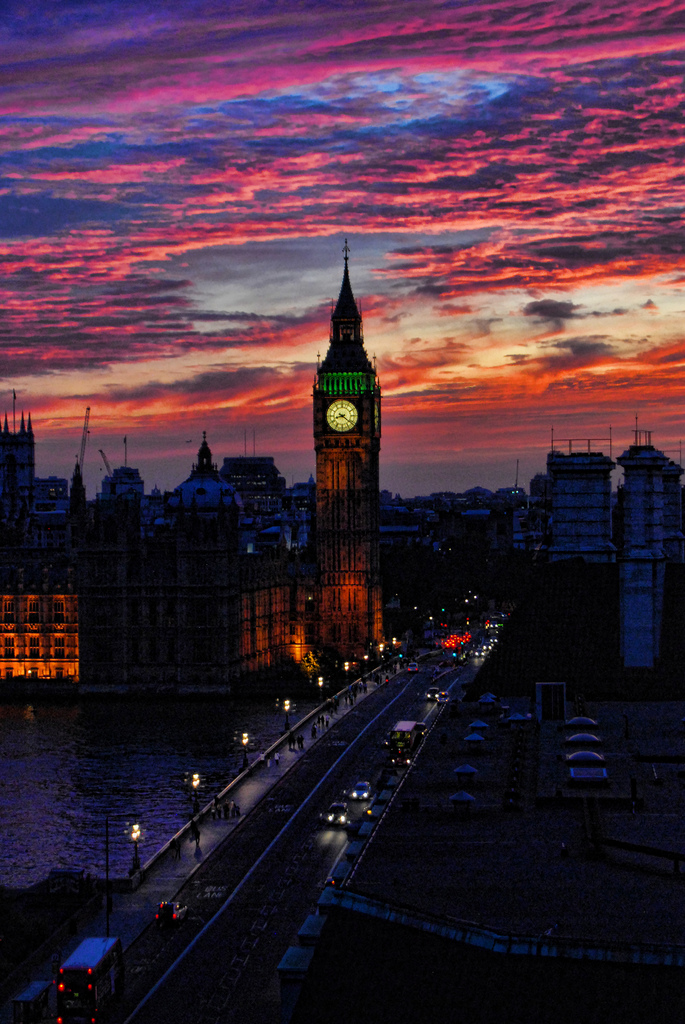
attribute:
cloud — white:
[474, 279, 675, 341]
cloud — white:
[30, 337, 320, 398]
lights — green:
[319, 368, 367, 394]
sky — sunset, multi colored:
[3, 0, 684, 493]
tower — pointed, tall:
[308, 234, 387, 664]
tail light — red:
[443, 642, 450, 648]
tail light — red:
[449, 642, 455, 646]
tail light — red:
[463, 630, 470, 636]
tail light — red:
[463, 635, 467, 641]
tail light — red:
[447, 632, 454, 638]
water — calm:
[4, 701, 316, 886]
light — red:
[153, 912, 160, 918]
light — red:
[169, 912, 177, 918]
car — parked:
[564, 746, 608, 768]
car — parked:
[560, 728, 608, 746]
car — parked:
[561, 712, 600, 730]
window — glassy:
[44, 635, 68, 662]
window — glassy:
[45, 598, 72, 625]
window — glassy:
[20, 592, 49, 634]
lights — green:
[315, 371, 381, 400]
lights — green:
[301, 367, 381, 405]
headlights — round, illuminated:
[320, 809, 352, 831]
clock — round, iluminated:
[314, 393, 365, 444]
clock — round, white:
[324, 398, 367, 436]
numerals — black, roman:
[322, 402, 363, 438]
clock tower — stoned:
[297, 236, 389, 690]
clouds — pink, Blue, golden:
[4, 6, 682, 492]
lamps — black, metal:
[110, 587, 494, 877]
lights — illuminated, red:
[46, 965, 103, 1023]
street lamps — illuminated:
[112, 587, 488, 892]